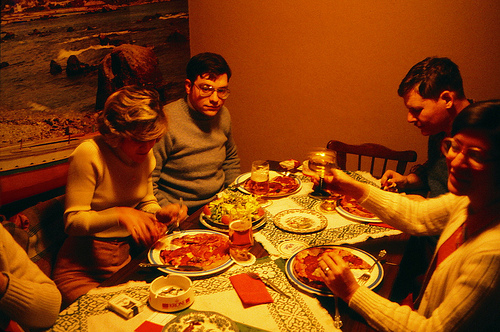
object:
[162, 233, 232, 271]
pizza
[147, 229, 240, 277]
plate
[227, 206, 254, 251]
glass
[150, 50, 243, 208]
man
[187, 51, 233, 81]
hair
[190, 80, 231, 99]
glasses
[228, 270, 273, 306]
napkin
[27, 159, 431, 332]
table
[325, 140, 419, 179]
chair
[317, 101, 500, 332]
woman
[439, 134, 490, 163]
glasses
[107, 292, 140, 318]
cigarettes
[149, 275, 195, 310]
ashtray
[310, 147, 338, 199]
wine glass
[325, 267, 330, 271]
wedding band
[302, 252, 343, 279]
slice of pizza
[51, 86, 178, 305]
woman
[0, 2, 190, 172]
painting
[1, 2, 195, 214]
wall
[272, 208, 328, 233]
plate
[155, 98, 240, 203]
sweater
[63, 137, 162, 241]
sweater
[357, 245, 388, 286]
fork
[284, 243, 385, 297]
plate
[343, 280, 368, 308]
wrist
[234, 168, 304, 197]
plate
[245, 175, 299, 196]
pizza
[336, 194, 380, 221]
plate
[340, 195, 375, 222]
pizza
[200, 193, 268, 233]
plate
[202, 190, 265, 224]
salad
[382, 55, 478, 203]
man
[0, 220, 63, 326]
person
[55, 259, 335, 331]
table cloth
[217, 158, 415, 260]
table cloth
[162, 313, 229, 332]
plate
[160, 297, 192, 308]
lettering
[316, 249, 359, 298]
hand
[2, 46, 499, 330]
family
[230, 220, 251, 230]
beer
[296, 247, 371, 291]
pizza